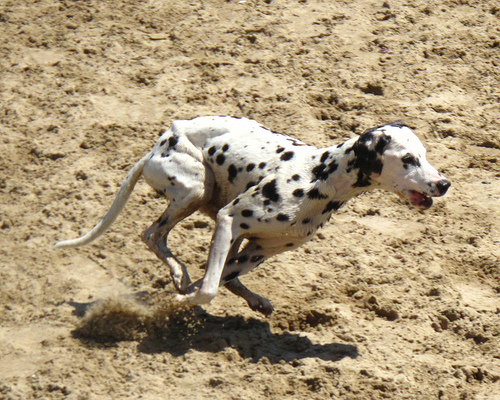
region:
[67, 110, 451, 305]
dog running on beach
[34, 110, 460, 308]
dalmation running on beach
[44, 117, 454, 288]
dog running on sand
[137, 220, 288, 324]
legs of dog running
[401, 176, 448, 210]
open mouth of dog running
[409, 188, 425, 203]
small orange tongue of dog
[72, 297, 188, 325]
sand being kicked up by dog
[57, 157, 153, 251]
long white tail of dog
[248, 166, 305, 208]
black spots on body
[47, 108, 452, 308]
the dog is running fast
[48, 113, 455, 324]
the dog is white with black spots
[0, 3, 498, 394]
the dirt covers the picture from top to bottom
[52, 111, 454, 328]
the dog is running with his mouth open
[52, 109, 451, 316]
the dog has a black spot over his eye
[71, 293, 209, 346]
the dirt is flying from the dog's paws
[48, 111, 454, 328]
the dog's paws are touching from running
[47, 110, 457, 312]
the tail of the dog is all white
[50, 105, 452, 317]
the dog is airborne from his speed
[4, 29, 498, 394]
footprints are seen throughout the dirt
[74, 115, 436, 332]
dalmation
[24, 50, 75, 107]
dry brown dirt on ground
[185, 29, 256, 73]
dry brown dirt on ground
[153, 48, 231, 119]
dry brown dirt on ground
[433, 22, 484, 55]
dry brown dirt on ground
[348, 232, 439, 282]
dry brown dirt on ground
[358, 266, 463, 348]
dry brown dirt on ground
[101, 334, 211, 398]
dry brown dirt on ground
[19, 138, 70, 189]
dry brown dirt on ground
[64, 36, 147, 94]
dry brown dirt on ground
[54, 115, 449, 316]
dog running on the sand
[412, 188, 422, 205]
tongue of dog sticking out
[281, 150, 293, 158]
black spot on the dog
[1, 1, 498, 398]
sand field under the dog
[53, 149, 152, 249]
tail of a dalmatian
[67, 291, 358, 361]
shadow of a dog on the sand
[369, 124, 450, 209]
head of a white dog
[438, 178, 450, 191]
black nose of a white dog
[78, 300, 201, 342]
sand flying in the air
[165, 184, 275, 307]
leg of a white dog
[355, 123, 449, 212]
head of a dalmatian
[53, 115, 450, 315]
dog running in the dirt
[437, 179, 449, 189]
nose of a dalmatian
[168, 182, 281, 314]
front leg of a dalmatian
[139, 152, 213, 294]
back leg of a dalmatian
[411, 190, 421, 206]
tongue of a dalmatian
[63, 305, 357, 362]
shadow of a dog running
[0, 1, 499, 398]
sand covering the ground